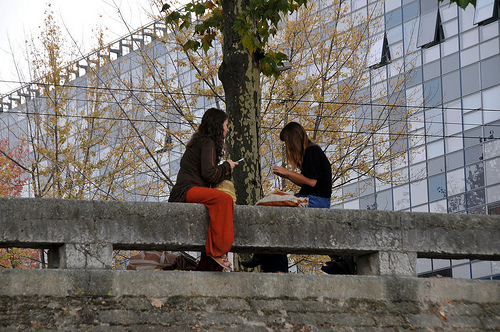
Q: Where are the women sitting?
A: Concrete bench.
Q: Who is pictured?
A: Two women.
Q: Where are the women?
A: Sitting on a wall.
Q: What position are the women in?
A: Sitting.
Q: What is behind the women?
A: Building.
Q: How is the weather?
A: Hazy.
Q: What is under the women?
A: Stone wall.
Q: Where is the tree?
A: Behind the women.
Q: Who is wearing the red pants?
A: The woman who is straddling the wall.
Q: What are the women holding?
A: Cell phones.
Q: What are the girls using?
A: Phones.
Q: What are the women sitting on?
A: A ledge.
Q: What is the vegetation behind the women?
A: Trees.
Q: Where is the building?
A: Behind the trees.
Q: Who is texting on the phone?
A: The girl.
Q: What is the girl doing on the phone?
A: Texting.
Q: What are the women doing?
A: Sitting down.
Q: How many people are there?
A: 2.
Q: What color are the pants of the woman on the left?
A: Red.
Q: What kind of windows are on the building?
A: Mirrored.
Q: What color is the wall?
A: Gray.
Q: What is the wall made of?
A: Stone.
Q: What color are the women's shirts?
A: Black.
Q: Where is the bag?
A: Between the women.